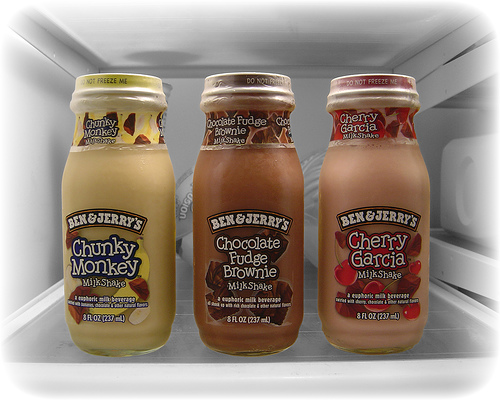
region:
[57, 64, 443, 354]
three bottles of flavored milk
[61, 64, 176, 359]
bottle on the left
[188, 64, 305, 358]
bottle in the middle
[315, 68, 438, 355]
bottle on the right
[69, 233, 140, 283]
flavor of the left bottle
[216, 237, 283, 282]
flavor of the middle bottle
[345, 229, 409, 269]
flavor of the right bottle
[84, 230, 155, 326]
image of a banana on the label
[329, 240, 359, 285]
image of a cherry on the label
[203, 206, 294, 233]
name of the company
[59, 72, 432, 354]
Three jars of milkshake together.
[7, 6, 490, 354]
the jars are inside of a white cooler.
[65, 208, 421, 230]
Three Ben&Jerry's logos.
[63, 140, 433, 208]
Three different colors in the jars.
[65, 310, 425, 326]
Each label is for 8 ounces.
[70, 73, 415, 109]
Three lids with seal tape on.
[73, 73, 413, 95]
Three lids say "do not freeze me".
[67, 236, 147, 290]
Says Chunky monkey milkshake.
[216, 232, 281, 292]
Says choclate fudge brownie milkshake.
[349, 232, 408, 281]
Says cherry Garcia milk shake.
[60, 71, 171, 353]
The flavor of the milkshake is Chunky Monkey.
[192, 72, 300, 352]
The flavor of the milkshake is Chocolate Fudge Brownie.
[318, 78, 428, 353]
The milkshake flavor is Cherry Garcia.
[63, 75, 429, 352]
The three milk shake are in the refrigerator.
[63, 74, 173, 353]
The milkshake is color beige.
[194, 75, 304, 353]
The milkshake is color brown.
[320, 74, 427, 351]
The milkshake is color pink.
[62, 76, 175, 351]
The milkshake is in a glass bottle.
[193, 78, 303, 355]
The milkshake brand is Ben & Jerry's.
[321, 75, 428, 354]
The milkshake contains 237 ml.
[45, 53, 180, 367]
a chunky monkey milkshake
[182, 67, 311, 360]
a chocalate fudge brownie milkshake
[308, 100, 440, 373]
ben and jerry's cherry garcia milkshake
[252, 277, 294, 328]
sticker of a brownie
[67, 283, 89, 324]
sticker of a chocolate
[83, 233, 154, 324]
sticker of a banana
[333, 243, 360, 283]
sticker of a cherry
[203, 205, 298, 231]
ben & jerry's logo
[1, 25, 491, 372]
refrigerator shelf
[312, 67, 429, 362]
glass bottle containing a milkshake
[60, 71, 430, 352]
the milkshakes in glass jars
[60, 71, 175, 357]
the glass jar filled with milkshake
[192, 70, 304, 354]
the glass jar filled with milkshake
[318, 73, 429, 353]
the glass jar filled with milkshake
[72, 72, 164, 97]
the cap on the glass jar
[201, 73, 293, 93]
the cap on the glass jar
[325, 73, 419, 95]
the cap on the glass jar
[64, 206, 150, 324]
the label on the glass jar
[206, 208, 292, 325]
the label on the glass jar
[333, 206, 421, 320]
the label on the glass jar